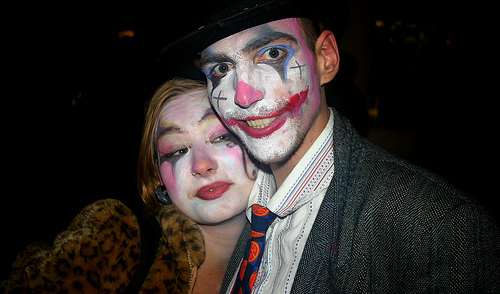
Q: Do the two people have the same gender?
A: No, they are both male and female.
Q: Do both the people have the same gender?
A: No, they are both male and female.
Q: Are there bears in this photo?
A: No, there are no bears.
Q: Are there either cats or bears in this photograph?
A: No, there are no bears or cats.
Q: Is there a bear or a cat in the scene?
A: No, there are no bears or cats.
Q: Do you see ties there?
A: Yes, there is a tie.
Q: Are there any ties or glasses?
A: Yes, there is a tie.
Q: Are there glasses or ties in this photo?
A: Yes, there is a tie.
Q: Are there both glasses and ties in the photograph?
A: No, there is a tie but no glasses.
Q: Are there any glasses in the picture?
A: No, there are no glasses.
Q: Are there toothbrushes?
A: No, there are no toothbrushes.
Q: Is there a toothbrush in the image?
A: No, there are no toothbrushes.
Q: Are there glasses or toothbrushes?
A: No, there are no toothbrushes or glasses.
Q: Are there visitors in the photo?
A: No, there are no visitors.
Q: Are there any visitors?
A: No, there are no visitors.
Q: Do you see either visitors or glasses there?
A: No, there are no visitors or glasses.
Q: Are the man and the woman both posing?
A: Yes, both the man and the woman are posing.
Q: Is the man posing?
A: Yes, the man is posing.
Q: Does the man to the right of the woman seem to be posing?
A: Yes, the man is posing.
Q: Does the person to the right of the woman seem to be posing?
A: Yes, the man is posing.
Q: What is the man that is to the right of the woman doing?
A: The man is posing.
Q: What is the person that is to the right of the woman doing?
A: The man is posing.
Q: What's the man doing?
A: The man is posing.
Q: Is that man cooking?
A: No, the man is posing.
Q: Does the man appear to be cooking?
A: No, the man is posing.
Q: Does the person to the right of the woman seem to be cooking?
A: No, the man is posing.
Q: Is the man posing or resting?
A: The man is posing.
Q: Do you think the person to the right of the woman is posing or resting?
A: The man is posing.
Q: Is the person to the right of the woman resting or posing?
A: The man is posing.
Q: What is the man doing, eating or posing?
A: The man is posing.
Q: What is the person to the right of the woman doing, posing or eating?
A: The man is posing.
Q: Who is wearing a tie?
A: The man is wearing a tie.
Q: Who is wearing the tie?
A: The man is wearing a tie.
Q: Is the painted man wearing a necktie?
A: Yes, the man is wearing a necktie.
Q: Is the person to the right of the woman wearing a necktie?
A: Yes, the man is wearing a necktie.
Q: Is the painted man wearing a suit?
A: No, the man is wearing a necktie.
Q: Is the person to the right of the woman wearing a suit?
A: No, the man is wearing a necktie.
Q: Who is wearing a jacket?
A: The man is wearing a jacket.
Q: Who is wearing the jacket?
A: The man is wearing a jacket.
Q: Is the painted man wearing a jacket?
A: Yes, the man is wearing a jacket.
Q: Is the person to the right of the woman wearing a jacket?
A: Yes, the man is wearing a jacket.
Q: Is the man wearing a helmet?
A: No, the man is wearing a jacket.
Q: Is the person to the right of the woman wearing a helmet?
A: No, the man is wearing a jacket.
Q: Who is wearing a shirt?
A: The man is wearing a shirt.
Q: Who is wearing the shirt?
A: The man is wearing a shirt.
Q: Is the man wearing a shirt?
A: Yes, the man is wearing a shirt.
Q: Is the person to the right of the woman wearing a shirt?
A: Yes, the man is wearing a shirt.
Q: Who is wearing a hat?
A: The man is wearing a hat.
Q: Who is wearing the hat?
A: The man is wearing a hat.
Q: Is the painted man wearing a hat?
A: Yes, the man is wearing a hat.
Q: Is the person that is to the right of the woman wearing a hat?
A: Yes, the man is wearing a hat.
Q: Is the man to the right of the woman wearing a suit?
A: No, the man is wearing a hat.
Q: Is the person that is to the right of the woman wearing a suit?
A: No, the man is wearing a hat.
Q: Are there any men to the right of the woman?
A: Yes, there is a man to the right of the woman.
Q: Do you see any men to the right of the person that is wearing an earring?
A: Yes, there is a man to the right of the woman.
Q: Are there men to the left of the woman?
A: No, the man is to the right of the woman.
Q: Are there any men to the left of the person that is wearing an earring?
A: No, the man is to the right of the woman.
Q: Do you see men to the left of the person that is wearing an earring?
A: No, the man is to the right of the woman.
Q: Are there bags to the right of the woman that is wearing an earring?
A: No, there is a man to the right of the woman.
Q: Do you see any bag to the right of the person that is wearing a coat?
A: No, there is a man to the right of the woman.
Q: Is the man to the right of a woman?
A: Yes, the man is to the right of a woman.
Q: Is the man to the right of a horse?
A: No, the man is to the right of a woman.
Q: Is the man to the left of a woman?
A: No, the man is to the right of a woman.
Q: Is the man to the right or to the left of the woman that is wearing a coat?
A: The man is to the right of the woman.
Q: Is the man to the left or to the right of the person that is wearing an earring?
A: The man is to the right of the woman.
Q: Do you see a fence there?
A: No, there are no fences.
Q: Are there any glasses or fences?
A: No, there are no fences or glasses.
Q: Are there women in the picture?
A: Yes, there is a woman.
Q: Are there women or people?
A: Yes, there is a woman.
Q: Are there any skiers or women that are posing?
A: Yes, the woman is posing.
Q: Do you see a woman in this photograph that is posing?
A: Yes, there is a woman that is posing.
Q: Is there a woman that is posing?
A: Yes, there is a woman that is posing.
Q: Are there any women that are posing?
A: Yes, there is a woman that is posing.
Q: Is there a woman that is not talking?
A: Yes, there is a woman that is posing.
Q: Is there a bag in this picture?
A: No, there are no bags.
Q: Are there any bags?
A: No, there are no bags.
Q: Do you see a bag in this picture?
A: No, there are no bags.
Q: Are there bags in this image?
A: No, there are no bags.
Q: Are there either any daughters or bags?
A: No, there are no bags or daughters.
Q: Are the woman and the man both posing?
A: Yes, both the woman and the man are posing.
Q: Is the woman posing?
A: Yes, the woman is posing.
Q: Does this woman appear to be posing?
A: Yes, the woman is posing.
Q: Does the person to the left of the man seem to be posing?
A: Yes, the woman is posing.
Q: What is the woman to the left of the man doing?
A: The woman is posing.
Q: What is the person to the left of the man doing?
A: The woman is posing.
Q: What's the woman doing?
A: The woman is posing.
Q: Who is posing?
A: The woman is posing.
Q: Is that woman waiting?
A: No, the woman is posing.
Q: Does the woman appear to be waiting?
A: No, the woman is posing.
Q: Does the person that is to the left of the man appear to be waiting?
A: No, the woman is posing.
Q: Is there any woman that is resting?
A: No, there is a woman but she is posing.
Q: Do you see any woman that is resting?
A: No, there is a woman but she is posing.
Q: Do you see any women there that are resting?
A: No, there is a woman but she is posing.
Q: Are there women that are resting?
A: No, there is a woman but she is posing.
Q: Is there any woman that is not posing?
A: No, there is a woman but she is posing.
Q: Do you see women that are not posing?
A: No, there is a woman but she is posing.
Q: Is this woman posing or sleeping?
A: The woman is posing.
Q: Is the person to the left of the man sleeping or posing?
A: The woman is posing.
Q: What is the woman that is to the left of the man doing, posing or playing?
A: The woman is posing.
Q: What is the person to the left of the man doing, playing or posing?
A: The woman is posing.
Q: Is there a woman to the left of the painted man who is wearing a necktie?
A: Yes, there is a woman to the left of the man.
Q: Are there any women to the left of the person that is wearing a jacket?
A: Yes, there is a woman to the left of the man.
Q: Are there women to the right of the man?
A: No, the woman is to the left of the man.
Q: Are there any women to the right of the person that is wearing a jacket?
A: No, the woman is to the left of the man.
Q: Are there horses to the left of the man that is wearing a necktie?
A: No, there is a woman to the left of the man.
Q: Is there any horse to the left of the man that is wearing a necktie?
A: No, there is a woman to the left of the man.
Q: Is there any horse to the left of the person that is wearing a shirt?
A: No, there is a woman to the left of the man.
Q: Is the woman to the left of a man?
A: Yes, the woman is to the left of a man.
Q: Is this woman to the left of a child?
A: No, the woman is to the left of a man.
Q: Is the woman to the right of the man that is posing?
A: No, the woman is to the left of the man.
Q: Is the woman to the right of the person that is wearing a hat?
A: No, the woman is to the left of the man.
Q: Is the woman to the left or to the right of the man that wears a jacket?
A: The woman is to the left of the man.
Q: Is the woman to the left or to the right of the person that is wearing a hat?
A: The woman is to the left of the man.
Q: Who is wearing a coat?
A: The woman is wearing a coat.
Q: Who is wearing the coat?
A: The woman is wearing a coat.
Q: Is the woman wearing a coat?
A: Yes, the woman is wearing a coat.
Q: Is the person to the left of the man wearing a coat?
A: Yes, the woman is wearing a coat.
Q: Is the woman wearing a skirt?
A: No, the woman is wearing a coat.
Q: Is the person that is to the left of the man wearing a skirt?
A: No, the woman is wearing a coat.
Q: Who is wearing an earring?
A: The woman is wearing an earring.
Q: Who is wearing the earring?
A: The woman is wearing an earring.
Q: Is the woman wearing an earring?
A: Yes, the woman is wearing an earring.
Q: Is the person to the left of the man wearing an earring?
A: Yes, the woman is wearing an earring.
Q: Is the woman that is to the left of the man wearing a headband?
A: No, the woman is wearing an earring.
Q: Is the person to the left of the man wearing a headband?
A: No, the woman is wearing an earring.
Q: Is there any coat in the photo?
A: Yes, there is a coat.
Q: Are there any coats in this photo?
A: Yes, there is a coat.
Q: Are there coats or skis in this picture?
A: Yes, there is a coat.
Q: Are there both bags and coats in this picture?
A: No, there is a coat but no bags.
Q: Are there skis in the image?
A: No, there are no skis.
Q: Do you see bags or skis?
A: No, there are no skis or bags.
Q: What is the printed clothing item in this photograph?
A: The clothing item is a coat.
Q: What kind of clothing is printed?
A: The clothing is a coat.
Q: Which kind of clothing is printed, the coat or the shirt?
A: The coat is printed.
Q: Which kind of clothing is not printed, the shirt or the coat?
A: The shirt is not printed.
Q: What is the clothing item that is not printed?
A: The clothing item is a shirt.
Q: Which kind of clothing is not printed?
A: The clothing is a shirt.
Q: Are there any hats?
A: Yes, there is a hat.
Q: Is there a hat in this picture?
A: Yes, there is a hat.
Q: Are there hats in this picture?
A: Yes, there is a hat.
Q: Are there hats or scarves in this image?
A: Yes, there is a hat.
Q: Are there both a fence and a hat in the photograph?
A: No, there is a hat but no fences.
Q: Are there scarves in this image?
A: No, there are no scarves.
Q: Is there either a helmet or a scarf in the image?
A: No, there are no scarves or helmets.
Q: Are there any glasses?
A: No, there are no glasses.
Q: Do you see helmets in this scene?
A: No, there are no helmets.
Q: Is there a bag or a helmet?
A: No, there are no helmets or bags.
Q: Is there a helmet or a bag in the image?
A: No, there are no helmets or bags.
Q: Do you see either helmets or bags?
A: No, there are no helmets or bags.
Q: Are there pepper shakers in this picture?
A: No, there are no pepper shakers.